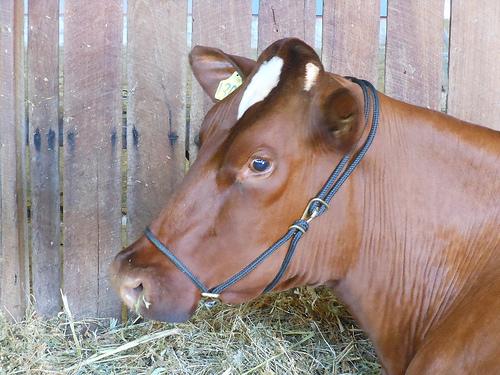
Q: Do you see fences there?
A: Yes, there is a fence.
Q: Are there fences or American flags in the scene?
A: Yes, there is a fence.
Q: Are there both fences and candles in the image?
A: No, there is a fence but no candles.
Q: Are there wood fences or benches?
A: Yes, there is a wood fence.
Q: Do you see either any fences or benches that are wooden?
A: Yes, the fence is wooden.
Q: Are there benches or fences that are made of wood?
A: Yes, the fence is made of wood.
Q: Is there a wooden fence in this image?
A: Yes, there is a wood fence.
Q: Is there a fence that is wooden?
A: Yes, there is a fence that is wooden.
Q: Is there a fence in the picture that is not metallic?
A: Yes, there is a wooden fence.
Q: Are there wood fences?
A: Yes, there is a fence that is made of wood.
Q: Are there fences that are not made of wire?
A: Yes, there is a fence that is made of wood.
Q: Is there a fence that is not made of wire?
A: Yes, there is a fence that is made of wood.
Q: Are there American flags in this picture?
A: No, there are no American flags.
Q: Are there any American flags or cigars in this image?
A: No, there are no American flags or cigars.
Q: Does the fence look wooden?
A: Yes, the fence is wooden.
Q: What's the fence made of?
A: The fence is made of wood.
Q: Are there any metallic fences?
A: No, there is a fence but it is wooden.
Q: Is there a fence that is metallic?
A: No, there is a fence but it is wooden.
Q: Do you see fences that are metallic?
A: No, there is a fence but it is wooden.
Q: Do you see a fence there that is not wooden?
A: No, there is a fence but it is wooden.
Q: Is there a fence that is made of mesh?
A: No, there is a fence but it is made of wood.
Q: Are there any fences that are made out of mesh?
A: No, there is a fence but it is made of wood.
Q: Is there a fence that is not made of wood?
A: No, there is a fence but it is made of wood.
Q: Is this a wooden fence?
A: Yes, this is a wooden fence.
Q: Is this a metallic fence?
A: No, this is a wooden fence.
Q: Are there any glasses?
A: No, there are no glasses.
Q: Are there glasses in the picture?
A: No, there are no glasses.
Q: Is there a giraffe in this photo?
A: No, there are no giraffes.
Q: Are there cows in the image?
A: Yes, there is a cow.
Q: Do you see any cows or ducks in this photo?
A: Yes, there is a cow.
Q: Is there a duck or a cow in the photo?
A: Yes, there is a cow.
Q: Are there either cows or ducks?
A: Yes, there is a cow.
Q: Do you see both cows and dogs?
A: No, there is a cow but no dogs.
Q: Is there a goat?
A: No, there are no goats.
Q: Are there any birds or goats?
A: No, there are no goats or birds.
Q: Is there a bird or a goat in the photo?
A: No, there are no goats or birds.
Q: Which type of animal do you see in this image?
A: The animal is a cow.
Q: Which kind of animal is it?
A: The animal is a cow.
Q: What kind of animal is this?
A: That is a cow.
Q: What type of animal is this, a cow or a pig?
A: That is a cow.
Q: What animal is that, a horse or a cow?
A: That is a cow.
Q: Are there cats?
A: No, there are no cats.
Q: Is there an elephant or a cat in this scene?
A: No, there are no cats or elephants.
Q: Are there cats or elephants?
A: No, there are no cats or elephants.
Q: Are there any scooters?
A: No, there are no scooters.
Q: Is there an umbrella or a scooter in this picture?
A: No, there are no scooters or umbrellas.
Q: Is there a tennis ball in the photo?
A: No, there are no tennis balls.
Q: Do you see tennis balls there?
A: No, there are no tennis balls.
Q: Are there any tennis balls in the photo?
A: No, there are no tennis balls.